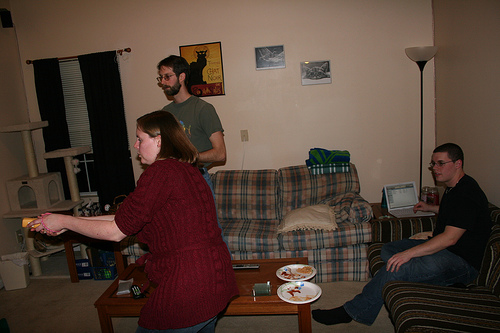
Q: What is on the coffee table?
A: Styrofoam plates.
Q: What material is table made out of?
A: Wood.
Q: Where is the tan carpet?
A: Floor.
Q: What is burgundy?
A: Woman's sweater.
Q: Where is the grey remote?
A: On the table.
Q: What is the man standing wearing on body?
A: Green t-shirt.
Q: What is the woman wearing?
A: Burgundy sweater.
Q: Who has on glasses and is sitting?
A: Boy on couch.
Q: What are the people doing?
A: Playing wii.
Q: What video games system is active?
A: Nintendo wii.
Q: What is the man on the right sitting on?
A: Couch.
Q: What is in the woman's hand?
A: Wii remote.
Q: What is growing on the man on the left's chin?
A: Beard.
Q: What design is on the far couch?
A: Plaid.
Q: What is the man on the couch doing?
A: Watching the two other people play video games.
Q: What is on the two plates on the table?
A: Food residue.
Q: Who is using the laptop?
A: The man on the striped couch.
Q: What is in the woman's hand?
A: A video game controller.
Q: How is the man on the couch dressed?
A: T-shirt and jeans.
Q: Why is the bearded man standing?
A: He is playing a video game with the woman.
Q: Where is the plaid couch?
A: Behind the bearded man.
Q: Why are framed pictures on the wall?
A: To decorate the room.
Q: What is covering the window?
A: Black curtains and white window blinds.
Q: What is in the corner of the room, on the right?
A: A lamp.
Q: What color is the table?
A: Brown.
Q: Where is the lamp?
A: Right side.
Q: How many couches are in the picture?
A: Two.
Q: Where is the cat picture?
A: On the wall.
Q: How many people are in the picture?
A: Three.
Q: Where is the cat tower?
A: Left side.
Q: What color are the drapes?
A: Black.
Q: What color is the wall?
A: Tan.